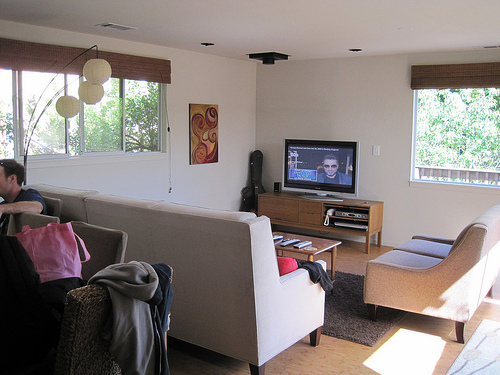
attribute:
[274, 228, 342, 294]
coffee stand — wooden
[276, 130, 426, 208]
television — flat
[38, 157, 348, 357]
sofa — beige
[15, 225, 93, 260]
handles — pink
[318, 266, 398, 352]
area rug — brown, dark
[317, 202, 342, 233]
telephone — white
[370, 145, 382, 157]
panel — white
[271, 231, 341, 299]
coffee table — wooden, brown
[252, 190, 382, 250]
entertainment stand — wooden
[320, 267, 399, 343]
rug — brown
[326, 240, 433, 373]
floors — hardwood, brown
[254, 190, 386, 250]
television stand — long, wooden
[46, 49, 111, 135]
floor lamp — lantern style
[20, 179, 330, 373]
couch — white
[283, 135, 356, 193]
screen — flat